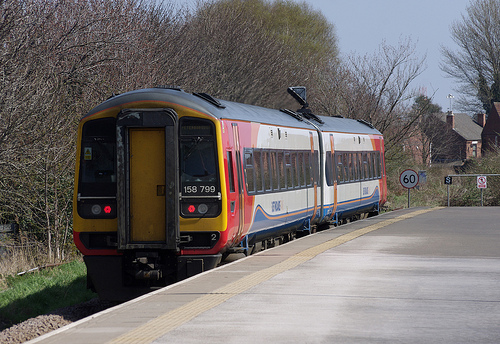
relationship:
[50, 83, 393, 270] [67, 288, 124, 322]
train on track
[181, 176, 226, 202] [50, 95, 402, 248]
numbers are on a train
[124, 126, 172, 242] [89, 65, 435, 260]
door on train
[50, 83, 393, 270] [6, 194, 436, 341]
train on track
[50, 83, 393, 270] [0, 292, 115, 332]
train on train track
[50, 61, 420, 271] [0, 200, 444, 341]
train on tracks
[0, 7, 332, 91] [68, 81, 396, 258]
trees lining tracks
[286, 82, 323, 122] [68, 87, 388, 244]
antenna on top of train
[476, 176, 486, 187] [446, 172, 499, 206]
sign hanging on fence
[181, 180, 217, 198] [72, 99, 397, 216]
numbers on front of train